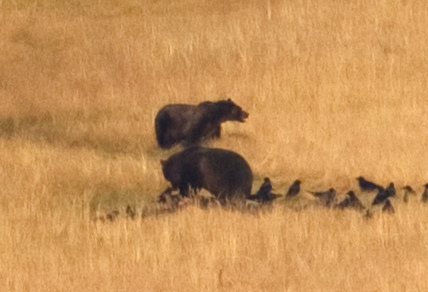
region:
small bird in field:
[260, 180, 272, 195]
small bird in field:
[287, 180, 302, 197]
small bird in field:
[312, 188, 335, 197]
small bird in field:
[339, 198, 351, 213]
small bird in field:
[351, 191, 363, 207]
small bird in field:
[355, 177, 380, 192]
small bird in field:
[374, 189, 387, 204]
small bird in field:
[389, 182, 401, 196]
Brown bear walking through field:
[159, 150, 256, 201]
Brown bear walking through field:
[155, 100, 246, 144]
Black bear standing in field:
[152, 97, 254, 150]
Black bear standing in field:
[158, 148, 253, 196]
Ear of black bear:
[221, 94, 234, 102]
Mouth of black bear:
[238, 108, 254, 126]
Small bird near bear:
[259, 174, 274, 208]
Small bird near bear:
[287, 170, 301, 207]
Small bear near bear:
[308, 184, 338, 204]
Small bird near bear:
[352, 170, 381, 193]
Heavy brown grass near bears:
[205, 235, 308, 275]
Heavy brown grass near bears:
[259, 33, 331, 73]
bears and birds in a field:
[0, 1, 423, 288]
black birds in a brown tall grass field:
[250, 168, 426, 221]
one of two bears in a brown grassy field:
[157, 145, 252, 207]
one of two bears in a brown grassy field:
[152, 96, 249, 149]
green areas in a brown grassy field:
[2, 96, 154, 206]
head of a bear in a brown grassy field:
[219, 97, 252, 130]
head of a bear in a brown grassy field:
[160, 156, 174, 185]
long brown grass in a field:
[5, 6, 420, 95]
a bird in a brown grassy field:
[283, 176, 303, 202]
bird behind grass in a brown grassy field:
[95, 206, 122, 229]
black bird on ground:
[257, 175, 272, 197]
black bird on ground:
[287, 182, 306, 199]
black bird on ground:
[315, 188, 337, 200]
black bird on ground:
[349, 194, 358, 212]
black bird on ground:
[354, 177, 379, 188]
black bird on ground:
[372, 189, 386, 201]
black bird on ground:
[383, 205, 395, 217]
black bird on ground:
[401, 188, 415, 202]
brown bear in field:
[162, 150, 256, 202]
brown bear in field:
[154, 100, 251, 146]